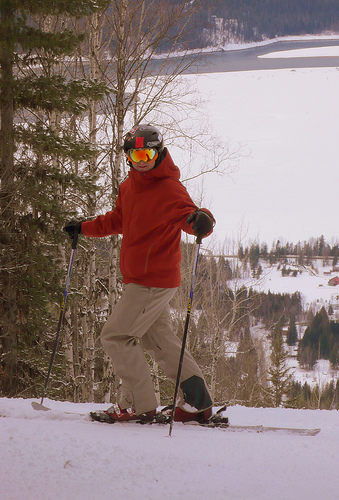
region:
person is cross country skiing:
[30, 123, 321, 436]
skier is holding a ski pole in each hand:
[38, 124, 215, 436]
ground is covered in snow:
[1, 396, 337, 498]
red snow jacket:
[78, 146, 211, 287]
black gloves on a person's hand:
[184, 209, 213, 238]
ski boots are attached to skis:
[29, 397, 323, 436]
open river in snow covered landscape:
[8, 38, 338, 123]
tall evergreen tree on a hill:
[2, 1, 104, 397]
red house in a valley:
[327, 274, 338, 285]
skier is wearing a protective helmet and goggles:
[64, 123, 216, 423]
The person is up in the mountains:
[54, 93, 268, 470]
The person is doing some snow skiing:
[60, 100, 294, 479]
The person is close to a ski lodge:
[41, 97, 286, 451]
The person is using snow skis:
[42, 84, 259, 469]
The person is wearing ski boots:
[36, 92, 284, 481]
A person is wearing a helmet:
[46, 108, 287, 466]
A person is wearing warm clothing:
[37, 99, 260, 479]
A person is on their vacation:
[37, 96, 314, 449]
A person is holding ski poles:
[32, 109, 262, 465]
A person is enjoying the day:
[35, 110, 278, 472]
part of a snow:
[306, 424, 307, 427]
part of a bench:
[216, 406, 219, 414]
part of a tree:
[250, 398, 255, 407]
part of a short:
[152, 391, 160, 406]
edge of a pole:
[166, 388, 192, 397]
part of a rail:
[41, 381, 44, 385]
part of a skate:
[130, 396, 138, 411]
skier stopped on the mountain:
[36, 121, 325, 441]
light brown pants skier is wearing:
[99, 278, 210, 412]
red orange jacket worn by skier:
[72, 170, 201, 280]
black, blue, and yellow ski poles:
[19, 227, 207, 428]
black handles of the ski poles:
[65, 224, 203, 247]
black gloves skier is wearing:
[64, 215, 213, 241]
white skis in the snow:
[32, 396, 319, 440]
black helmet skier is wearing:
[119, 128, 164, 147]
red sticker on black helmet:
[131, 135, 144, 147]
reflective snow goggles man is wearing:
[122, 149, 156, 159]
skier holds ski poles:
[28, 119, 218, 436]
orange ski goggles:
[123, 123, 167, 174]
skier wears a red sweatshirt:
[63, 123, 217, 433]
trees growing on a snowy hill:
[215, 232, 334, 391]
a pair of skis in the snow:
[9, 399, 322, 436]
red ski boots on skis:
[1, 391, 325, 440]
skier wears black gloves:
[63, 122, 224, 424]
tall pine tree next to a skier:
[0, 1, 217, 429]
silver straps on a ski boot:
[109, 400, 136, 419]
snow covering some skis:
[1, 396, 321, 438]